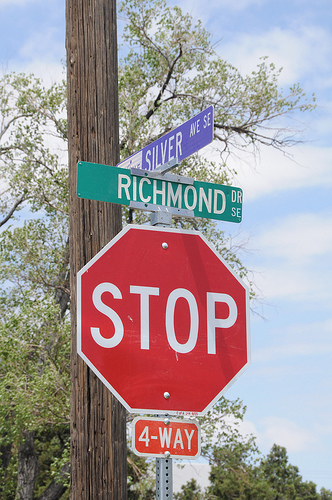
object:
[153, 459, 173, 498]
post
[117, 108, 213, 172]
signs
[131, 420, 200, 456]
sign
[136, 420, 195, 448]
4 way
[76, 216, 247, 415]
sign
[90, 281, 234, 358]
stop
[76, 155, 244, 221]
street sign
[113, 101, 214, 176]
street sign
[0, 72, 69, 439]
trees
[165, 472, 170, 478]
holes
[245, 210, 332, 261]
clouds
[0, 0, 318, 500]
tree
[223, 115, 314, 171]
branch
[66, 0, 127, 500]
pole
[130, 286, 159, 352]
letters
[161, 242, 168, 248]
bolt